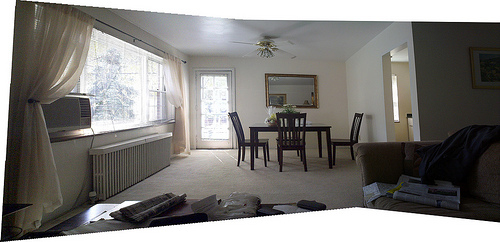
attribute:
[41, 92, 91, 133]
air conditioner — window unit, white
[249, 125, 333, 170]
table — for dining, dining room table, dark brown, for dining room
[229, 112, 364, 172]
chairs — for dining room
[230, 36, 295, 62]
fan — ceiling fan, white, moving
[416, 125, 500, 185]
blanket — cloth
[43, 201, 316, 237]
table — coffee table, cluttered, in foreground, desk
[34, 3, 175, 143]
window — large, giant, picture window, long, letting in light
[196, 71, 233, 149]
door — glass, to backyard, white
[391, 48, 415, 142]
another room — kitchen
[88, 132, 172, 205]
heater — radiator, wall radiator, long, white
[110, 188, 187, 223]
newspaper — rolled up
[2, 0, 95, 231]
curtains — white, gauzy, yellow, see-through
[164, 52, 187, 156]
curtains — white, gauzy, yellow, see-through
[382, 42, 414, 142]
passageway — without doors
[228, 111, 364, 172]
dining set — brown, wooden